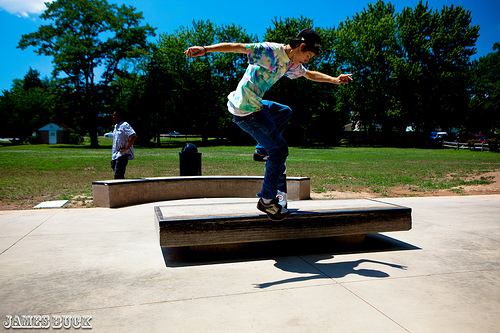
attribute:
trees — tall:
[0, 2, 497, 152]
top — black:
[175, 141, 199, 153]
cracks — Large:
[3, 212, 58, 263]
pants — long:
[222, 92, 294, 201]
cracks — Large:
[299, 261, 367, 304]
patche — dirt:
[386, 181, 418, 196]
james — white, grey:
[2, 312, 41, 331]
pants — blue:
[222, 92, 310, 200]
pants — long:
[112, 155, 127, 178]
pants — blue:
[113, 152, 128, 177]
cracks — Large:
[20, 202, 95, 286]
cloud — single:
[3, 2, 50, 16]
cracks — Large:
[175, 284, 290, 310]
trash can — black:
[179, 140, 202, 175]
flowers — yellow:
[350, 126, 437, 138]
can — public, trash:
[171, 147, 215, 177]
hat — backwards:
[284, 24, 327, 49]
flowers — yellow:
[72, 193, 84, 203]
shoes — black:
[257, 197, 290, 217]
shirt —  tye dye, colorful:
[227, 40, 304, 117]